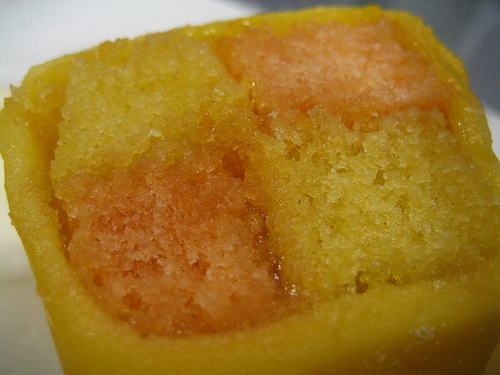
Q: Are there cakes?
A: Yes, there is a cake.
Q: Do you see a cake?
A: Yes, there is a cake.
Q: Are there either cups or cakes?
A: Yes, there is a cake.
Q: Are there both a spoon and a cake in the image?
A: No, there is a cake but no spoons.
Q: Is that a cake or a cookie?
A: That is a cake.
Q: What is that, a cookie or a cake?
A: That is a cake.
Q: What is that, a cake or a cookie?
A: That is a cake.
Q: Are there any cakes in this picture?
A: Yes, there is a cake.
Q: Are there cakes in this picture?
A: Yes, there is a cake.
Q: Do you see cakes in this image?
A: Yes, there is a cake.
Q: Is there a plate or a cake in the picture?
A: Yes, there is a cake.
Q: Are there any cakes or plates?
A: Yes, there is a cake.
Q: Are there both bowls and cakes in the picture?
A: No, there is a cake but no bowls.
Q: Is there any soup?
A: No, there is no soup.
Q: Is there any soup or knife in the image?
A: No, there are no soup or knives.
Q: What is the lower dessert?
A: The dessert is a cake.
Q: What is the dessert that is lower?
A: The dessert is a cake.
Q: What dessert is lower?
A: The dessert is a cake.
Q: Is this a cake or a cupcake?
A: This is a cake.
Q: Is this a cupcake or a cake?
A: This is a cake.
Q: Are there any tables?
A: Yes, there is a table.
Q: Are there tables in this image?
A: Yes, there is a table.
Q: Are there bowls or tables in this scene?
A: Yes, there is a table.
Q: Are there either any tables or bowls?
A: Yes, there is a table.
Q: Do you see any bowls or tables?
A: Yes, there is a table.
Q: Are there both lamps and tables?
A: No, there is a table but no lamps.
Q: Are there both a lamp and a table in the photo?
A: No, there is a table but no lamps.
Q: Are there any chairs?
A: No, there are no chairs.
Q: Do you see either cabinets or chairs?
A: No, there are no chairs or cabinets.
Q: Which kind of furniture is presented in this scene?
A: The furniture is a table.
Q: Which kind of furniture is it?
A: The piece of furniture is a table.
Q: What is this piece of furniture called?
A: This is a table.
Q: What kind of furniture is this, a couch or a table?
A: This is a table.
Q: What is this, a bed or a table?
A: This is a table.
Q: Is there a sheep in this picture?
A: Yes, there is a sheep.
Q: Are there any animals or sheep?
A: Yes, there is a sheep.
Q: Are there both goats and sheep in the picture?
A: No, there is a sheep but no goats.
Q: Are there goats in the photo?
A: No, there are no goats.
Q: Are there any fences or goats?
A: No, there are no goats or fences.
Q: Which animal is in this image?
A: The animal is a sheep.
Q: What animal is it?
A: The animal is a sheep.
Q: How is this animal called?
A: This is a sheep.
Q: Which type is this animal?
A: This is a sheep.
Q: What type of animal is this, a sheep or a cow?
A: This is a sheep.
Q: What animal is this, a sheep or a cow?
A: This is a sheep.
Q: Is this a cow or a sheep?
A: This is a sheep.